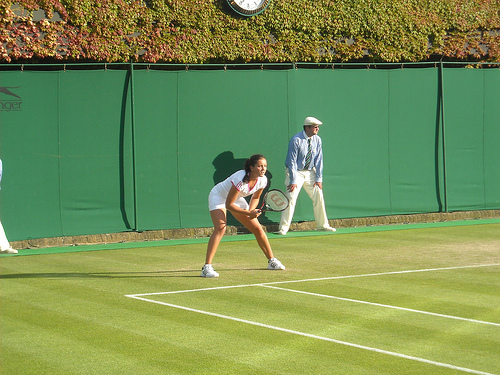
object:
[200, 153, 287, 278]
woman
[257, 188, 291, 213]
racquet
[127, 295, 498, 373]
lines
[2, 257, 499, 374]
tennis court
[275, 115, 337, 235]
man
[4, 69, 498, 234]
canvas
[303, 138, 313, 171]
tie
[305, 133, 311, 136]
neck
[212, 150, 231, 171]
shadow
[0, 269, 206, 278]
shadow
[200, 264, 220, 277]
shoes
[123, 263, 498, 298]
line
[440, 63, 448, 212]
pole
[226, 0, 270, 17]
clock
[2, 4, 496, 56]
ivy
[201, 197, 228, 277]
leg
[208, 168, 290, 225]
gear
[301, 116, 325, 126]
hat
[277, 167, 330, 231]
pants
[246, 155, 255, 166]
hair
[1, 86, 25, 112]
logo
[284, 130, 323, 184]
shirt